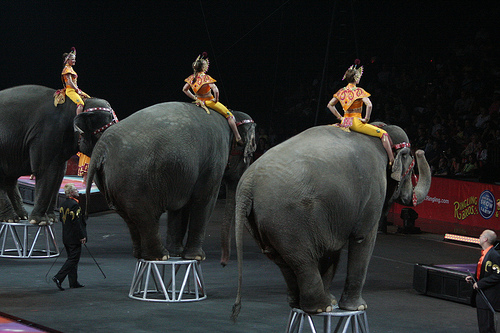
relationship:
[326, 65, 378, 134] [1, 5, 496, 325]
person enjoying outdoors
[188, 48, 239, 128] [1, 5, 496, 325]
person enjoying outdoors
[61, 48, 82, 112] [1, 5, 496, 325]
person enjoying outdoors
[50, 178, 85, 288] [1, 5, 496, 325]
person enjoying outdoors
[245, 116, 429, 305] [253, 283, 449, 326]
elephant standing inside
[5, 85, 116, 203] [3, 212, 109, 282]
elephant standing inside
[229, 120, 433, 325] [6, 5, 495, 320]
elephant in circus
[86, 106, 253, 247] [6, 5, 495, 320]
elephant in circus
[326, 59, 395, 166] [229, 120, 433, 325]
person sitting on elephant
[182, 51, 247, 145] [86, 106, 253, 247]
person sitting on elephant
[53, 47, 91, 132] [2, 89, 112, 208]
person sitting on elephant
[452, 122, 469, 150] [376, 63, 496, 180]
person in audience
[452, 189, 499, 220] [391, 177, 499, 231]
sign on banner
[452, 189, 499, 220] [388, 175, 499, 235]
sign on banner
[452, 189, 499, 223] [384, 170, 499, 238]
sign on banner